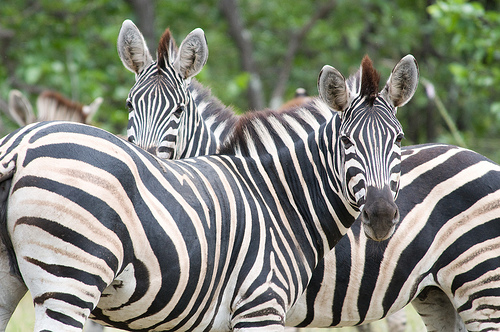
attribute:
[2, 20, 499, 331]
zebras — standing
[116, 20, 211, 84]
ears — white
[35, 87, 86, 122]
mane — brown, white, black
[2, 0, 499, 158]
blurred — green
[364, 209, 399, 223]
nose — black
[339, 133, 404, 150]
eyes — brown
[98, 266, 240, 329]
belly — big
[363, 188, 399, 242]
muzzle — black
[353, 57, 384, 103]
hair — brown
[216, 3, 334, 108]
branch — brown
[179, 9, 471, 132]
tree — lush